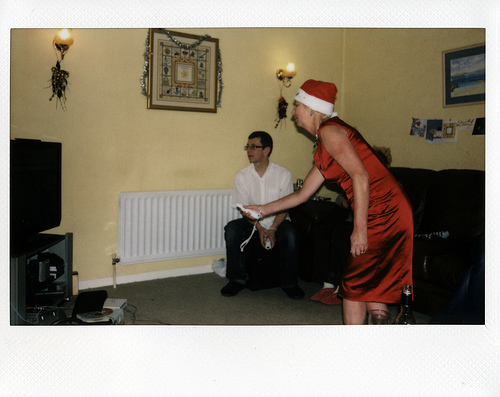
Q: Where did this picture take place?
A: It took place in the living room.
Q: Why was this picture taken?
A: To show how people are playing games.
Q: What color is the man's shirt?
A: The man's shirt is white.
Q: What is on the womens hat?
A: There is a red christmas hat on her head.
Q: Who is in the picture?
A: Three people are in the picture.